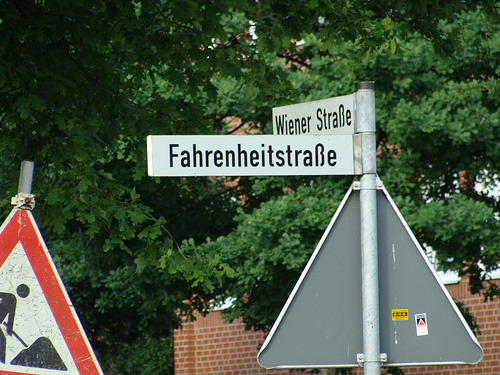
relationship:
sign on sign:
[271, 87, 378, 136] [271, 89, 374, 133]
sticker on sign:
[388, 306, 412, 323] [253, 175, 488, 369]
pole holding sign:
[354, 79, 382, 372] [271, 87, 378, 136]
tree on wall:
[1, 0, 498, 332] [173, 231, 498, 373]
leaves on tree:
[1, 2, 493, 252] [3, 0, 496, 371]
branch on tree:
[447, 158, 490, 201] [2, 33, 495, 325]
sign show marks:
[144, 134, 360, 176] [162, 141, 340, 168]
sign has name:
[271, 87, 378, 136] [264, 103, 355, 135]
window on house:
[420, 175, 465, 290] [171, 39, 496, 374]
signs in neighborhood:
[256, 178, 481, 374] [2, 4, 498, 373]